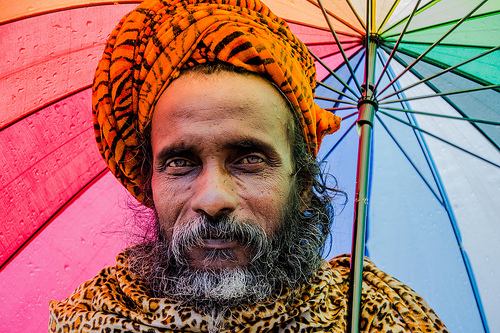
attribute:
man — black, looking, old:
[108, 72, 323, 289]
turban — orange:
[147, 6, 263, 62]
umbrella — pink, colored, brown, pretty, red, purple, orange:
[17, 28, 88, 209]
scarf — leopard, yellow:
[312, 287, 338, 326]